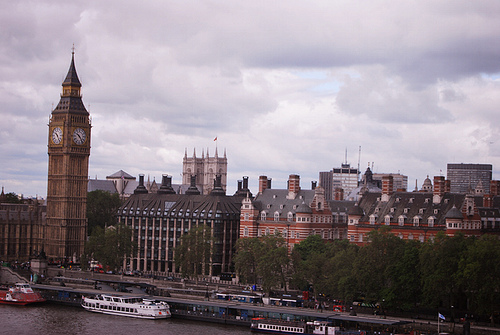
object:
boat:
[80, 293, 171, 320]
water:
[0, 300, 264, 335]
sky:
[0, 1, 500, 199]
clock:
[72, 128, 86, 145]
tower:
[44, 43, 93, 266]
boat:
[0, 283, 45, 306]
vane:
[71, 43, 76, 52]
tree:
[84, 224, 138, 273]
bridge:
[31, 284, 398, 335]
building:
[447, 163, 492, 194]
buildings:
[347, 176, 500, 248]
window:
[261, 213, 266, 221]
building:
[239, 174, 348, 256]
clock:
[52, 127, 63, 144]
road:
[47, 267, 500, 328]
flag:
[213, 136, 217, 142]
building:
[182, 136, 227, 195]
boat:
[248, 320, 340, 335]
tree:
[172, 223, 222, 285]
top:
[62, 44, 81, 84]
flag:
[439, 313, 446, 320]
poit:
[184, 147, 187, 158]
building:
[117, 172, 255, 283]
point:
[224, 148, 227, 158]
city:
[1, 44, 500, 335]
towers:
[201, 147, 204, 158]